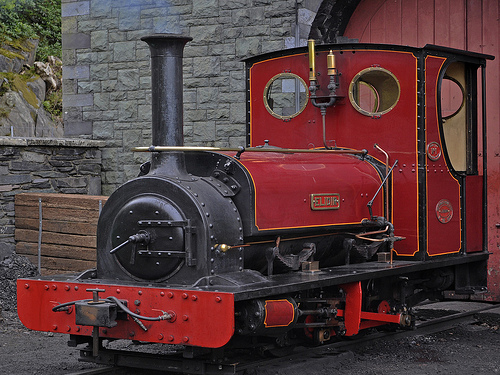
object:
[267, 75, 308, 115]
window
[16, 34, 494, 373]
train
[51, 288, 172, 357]
hitch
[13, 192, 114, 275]
stacked wood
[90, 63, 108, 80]
stone brick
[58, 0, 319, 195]
building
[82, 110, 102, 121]
brick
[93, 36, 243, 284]
engine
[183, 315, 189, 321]
bolt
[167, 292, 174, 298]
bolt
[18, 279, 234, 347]
front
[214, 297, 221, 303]
bolt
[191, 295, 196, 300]
bolt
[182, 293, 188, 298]
bolt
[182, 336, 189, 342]
bolt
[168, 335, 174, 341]
bolt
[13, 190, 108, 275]
bench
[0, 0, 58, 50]
green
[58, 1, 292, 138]
wall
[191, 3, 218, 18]
brick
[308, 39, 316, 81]
whistle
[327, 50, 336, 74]
whistle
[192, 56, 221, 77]
brick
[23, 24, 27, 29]
leaves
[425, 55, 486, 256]
door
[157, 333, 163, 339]
bolt